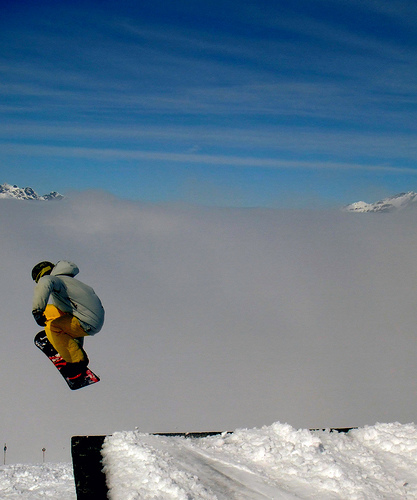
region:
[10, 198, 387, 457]
Thick cloud of haze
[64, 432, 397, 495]
A large black ramp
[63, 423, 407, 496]
Snow is on the ramp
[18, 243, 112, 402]
Snowboarder in a grey sweatshirt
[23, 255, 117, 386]
Snowboarder in yellow pants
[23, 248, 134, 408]
Snowboarder with a black helmet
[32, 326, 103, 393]
Red and black snowboard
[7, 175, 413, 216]
Rocky mountains with snow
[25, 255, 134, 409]
The snowboarder jumped off the ramp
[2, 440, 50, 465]
Two black narrow signs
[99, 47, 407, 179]
The sky is blue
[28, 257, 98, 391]
the person is snowboarding.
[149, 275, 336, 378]
The snow is white.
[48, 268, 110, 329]
Person is wearing a hoodie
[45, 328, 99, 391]
The snowboard is black and red.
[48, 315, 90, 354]
The person is wearing gold pants.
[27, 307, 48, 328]
The gloves are black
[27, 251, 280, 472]
Person jumped off the slope.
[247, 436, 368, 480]
The snow is fluffy and flanky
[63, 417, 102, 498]
the ramp is black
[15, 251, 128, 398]
a snowboarder in the air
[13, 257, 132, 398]
a snow boarder in yellow pants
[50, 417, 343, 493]
a ramp with snow on it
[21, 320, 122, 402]
a red and black snowboard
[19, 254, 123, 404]
a person performing a trick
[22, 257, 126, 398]
person jumping on a snowboard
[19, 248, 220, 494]
skier launches off a ramp on a snowboard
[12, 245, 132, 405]
skier with a green jacket and hood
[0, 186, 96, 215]
mountains with snow on them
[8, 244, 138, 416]
snowboarder with dark gloves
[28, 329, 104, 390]
a snowboard going off a jump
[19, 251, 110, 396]
a snowboarder that just went off a jump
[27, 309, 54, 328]
The black glove the snowboarder is wearing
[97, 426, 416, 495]
The white snow on the jump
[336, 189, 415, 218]
The top of the mountain in the background.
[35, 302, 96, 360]
The yellow snowpants of the man on the snowbaord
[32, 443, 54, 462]
A sign in the distance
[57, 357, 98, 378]
The boot of the guy on the snowboard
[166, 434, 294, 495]
The track left by the snowboard going off the jump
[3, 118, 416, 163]
The white clouds in the sky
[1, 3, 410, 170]
a blue sky with white clouds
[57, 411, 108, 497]
a black ramp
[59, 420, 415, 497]
a black ramp covered in snow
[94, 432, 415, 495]
snowboard tracks in snow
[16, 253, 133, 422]
a snow border doing trick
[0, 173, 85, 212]
top of snow covered mountain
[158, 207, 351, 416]
thick grey fog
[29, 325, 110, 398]
black and red snow board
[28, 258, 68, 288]
a black safety helmet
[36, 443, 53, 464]
a sign